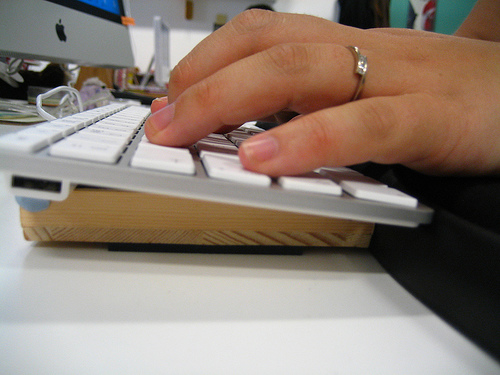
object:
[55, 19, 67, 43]
logo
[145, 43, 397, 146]
finger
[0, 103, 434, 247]
keyboard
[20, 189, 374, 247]
wood block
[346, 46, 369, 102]
ring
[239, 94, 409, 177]
finger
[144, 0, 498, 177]
hand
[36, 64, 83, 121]
wire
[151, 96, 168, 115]
finger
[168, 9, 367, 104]
finger